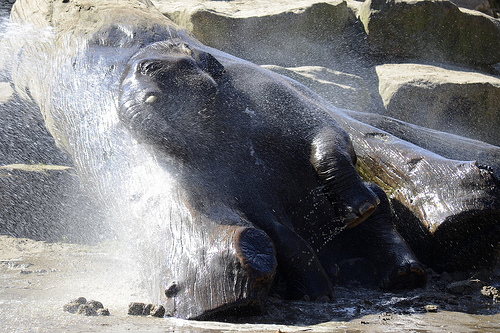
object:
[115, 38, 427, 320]
elephant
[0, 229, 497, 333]
ground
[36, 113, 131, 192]
water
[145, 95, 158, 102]
tusky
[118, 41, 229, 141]
head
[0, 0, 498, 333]
log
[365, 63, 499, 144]
rocks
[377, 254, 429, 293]
back left foot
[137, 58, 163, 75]
left eye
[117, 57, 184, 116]
face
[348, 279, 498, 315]
rocks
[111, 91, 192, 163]
trunk